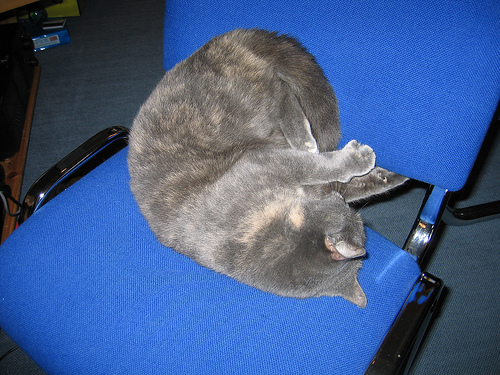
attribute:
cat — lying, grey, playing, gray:
[127, 28, 410, 308]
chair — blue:
[0, 1, 499, 372]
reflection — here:
[409, 225, 433, 249]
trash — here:
[30, 28, 73, 52]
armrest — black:
[18, 125, 130, 225]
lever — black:
[443, 202, 497, 227]